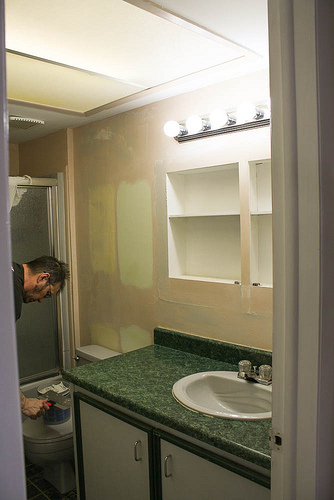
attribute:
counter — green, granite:
[62, 329, 272, 470]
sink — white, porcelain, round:
[173, 371, 272, 419]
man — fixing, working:
[12, 256, 70, 420]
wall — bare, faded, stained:
[71, 70, 272, 352]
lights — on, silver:
[163, 97, 271, 143]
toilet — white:
[23, 345, 122, 493]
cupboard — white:
[78, 401, 270, 500]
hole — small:
[273, 434, 282, 447]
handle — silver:
[132, 439, 142, 462]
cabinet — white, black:
[79, 396, 271, 498]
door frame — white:
[269, 2, 316, 498]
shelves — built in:
[167, 212, 272, 220]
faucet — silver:
[237, 371, 274, 386]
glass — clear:
[8, 188, 61, 386]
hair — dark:
[24, 256, 68, 292]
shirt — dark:
[13, 263, 24, 321]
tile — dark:
[28, 466, 76, 500]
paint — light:
[87, 179, 153, 354]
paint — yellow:
[116, 180, 152, 290]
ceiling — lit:
[6, 1, 270, 146]